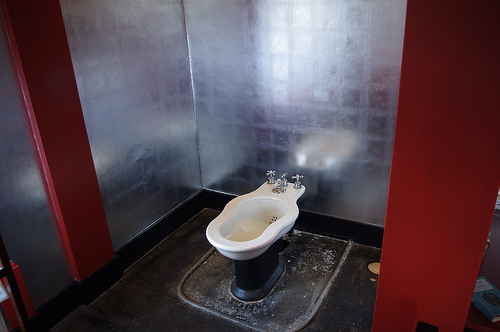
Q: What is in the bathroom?
A: The toilet.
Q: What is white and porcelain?
A: Toilet.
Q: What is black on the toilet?
A: Base under bow.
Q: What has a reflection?
A: Silver walls.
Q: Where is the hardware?
A: Back of toilet bowl.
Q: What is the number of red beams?
A: Two.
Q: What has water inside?
A: Toilet bowl.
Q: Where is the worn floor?
A: Around toilet base.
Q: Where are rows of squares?
A: Silver wall.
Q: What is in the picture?
A: A red stall divider.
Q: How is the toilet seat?
A: Short oddly shaped.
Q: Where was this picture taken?
A: In a bathroom.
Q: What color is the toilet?
A: White.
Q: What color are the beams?
A: Red.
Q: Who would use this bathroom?
A: People.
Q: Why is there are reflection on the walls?
A: They are metal.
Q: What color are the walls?
A: Silver.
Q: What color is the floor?
A: Black.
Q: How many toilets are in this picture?
A: One.